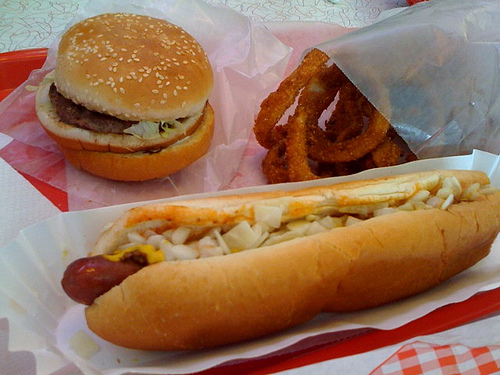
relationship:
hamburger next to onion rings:
[44, 27, 244, 212] [254, 12, 484, 161]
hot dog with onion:
[62, 167, 499, 354] [167, 243, 196, 263]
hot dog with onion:
[62, 167, 499, 354] [166, 221, 192, 246]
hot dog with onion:
[62, 167, 499, 354] [224, 220, 258, 252]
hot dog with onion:
[62, 167, 499, 354] [247, 203, 284, 231]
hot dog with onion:
[62, 167, 499, 354] [339, 213, 369, 229]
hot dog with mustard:
[62, 167, 499, 354] [97, 242, 167, 269]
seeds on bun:
[97, 43, 140, 73] [33, 12, 215, 178]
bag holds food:
[321, 30, 490, 163] [249, 35, 431, 172]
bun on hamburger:
[51, 12, 206, 118] [51, 97, 98, 129]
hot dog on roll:
[62, 167, 499, 354] [85, 167, 498, 356]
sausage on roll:
[71, 110, 101, 130] [74, 147, 174, 178]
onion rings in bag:
[252, 25, 455, 184] [300, 0, 497, 157]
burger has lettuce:
[32, 10, 218, 180] [120, 116, 187, 142]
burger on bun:
[32, 10, 218, 180] [51, 12, 206, 118]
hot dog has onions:
[62, 167, 499, 354] [159, 232, 204, 254]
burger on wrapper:
[32, 10, 218, 180] [2, 0, 499, 215]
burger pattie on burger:
[45, 83, 140, 139] [32, 10, 218, 180]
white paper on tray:
[0, 1, 497, 371] [0, 2, 498, 374]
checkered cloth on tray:
[368, 338, 498, 373] [0, 2, 498, 374]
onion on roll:
[224, 222, 256, 247] [85, 167, 498, 356]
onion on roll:
[169, 224, 191, 243] [85, 167, 498, 356]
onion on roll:
[247, 203, 284, 231] [85, 167, 498, 356]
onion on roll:
[301, 218, 323, 236] [85, 167, 498, 356]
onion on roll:
[434, 188, 452, 200] [85, 167, 498, 356]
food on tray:
[84, 182, 465, 312] [4, 42, 89, 177]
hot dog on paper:
[62, 167, 499, 354] [368, 340, 498, 374]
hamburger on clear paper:
[44, 27, 244, 212] [215, 12, 285, 79]